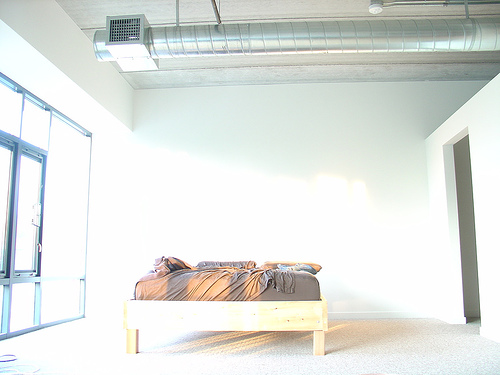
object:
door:
[451, 133, 478, 325]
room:
[0, 0, 500, 375]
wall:
[90, 79, 479, 321]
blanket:
[133, 254, 323, 301]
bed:
[120, 255, 331, 358]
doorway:
[434, 125, 486, 325]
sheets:
[131, 260, 321, 302]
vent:
[90, 9, 500, 88]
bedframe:
[123, 296, 327, 356]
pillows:
[196, 260, 322, 276]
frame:
[121, 254, 327, 355]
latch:
[18, 206, 45, 269]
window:
[0, 74, 90, 343]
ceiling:
[60, 0, 500, 126]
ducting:
[144, 19, 500, 83]